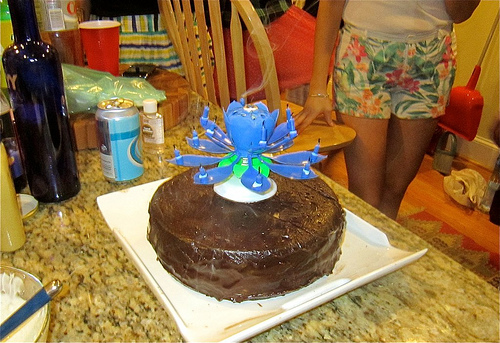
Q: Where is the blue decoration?
A: On top of the cake.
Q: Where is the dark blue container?
A: To the left of the cake.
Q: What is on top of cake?
A: Candles.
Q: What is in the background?
A: Broom with dustpan.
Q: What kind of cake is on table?
A: Chocolate cake.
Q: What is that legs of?
A: A person.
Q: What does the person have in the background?
A: Shorts.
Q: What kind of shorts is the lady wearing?
A: Flower shorts.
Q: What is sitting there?
A: Cake.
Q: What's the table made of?
A: Marble.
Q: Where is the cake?
A: On plate.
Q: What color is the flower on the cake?
A: Blue.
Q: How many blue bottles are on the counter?
A: One.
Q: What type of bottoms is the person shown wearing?
A: Shorts.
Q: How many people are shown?
A: One.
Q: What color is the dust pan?
A: Red.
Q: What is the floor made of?
A: Wood.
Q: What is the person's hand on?
A: Chair.